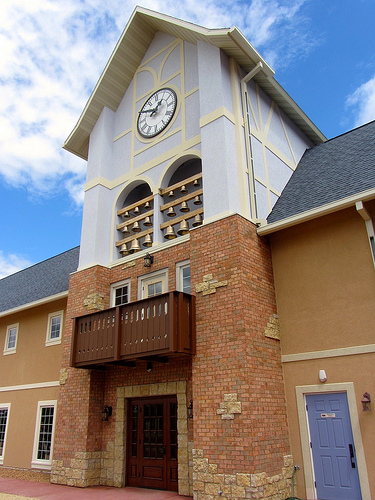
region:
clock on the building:
[128, 72, 192, 135]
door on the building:
[292, 377, 362, 498]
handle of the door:
[338, 437, 364, 476]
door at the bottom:
[117, 388, 187, 474]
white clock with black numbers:
[129, 85, 179, 142]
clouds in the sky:
[20, 87, 77, 143]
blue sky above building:
[321, 31, 357, 67]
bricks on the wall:
[213, 307, 246, 352]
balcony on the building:
[55, 290, 205, 376]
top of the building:
[119, 6, 170, 46]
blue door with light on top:
[289, 370, 373, 497]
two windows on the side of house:
[30, 304, 65, 483]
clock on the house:
[129, 83, 185, 139]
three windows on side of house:
[8, 310, 63, 469]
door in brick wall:
[94, 368, 199, 496]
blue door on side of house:
[290, 232, 374, 498]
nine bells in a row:
[112, 194, 152, 254]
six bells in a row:
[160, 179, 211, 215]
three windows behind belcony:
[67, 258, 202, 362]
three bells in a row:
[117, 199, 159, 220]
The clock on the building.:
[137, 87, 179, 138]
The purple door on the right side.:
[303, 391, 367, 498]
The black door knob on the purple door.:
[346, 438, 356, 471]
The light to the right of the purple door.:
[358, 385, 370, 417]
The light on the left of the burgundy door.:
[97, 400, 110, 424]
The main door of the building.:
[129, 397, 183, 492]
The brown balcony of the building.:
[68, 297, 192, 370]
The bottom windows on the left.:
[2, 403, 57, 467]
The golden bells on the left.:
[113, 181, 157, 251]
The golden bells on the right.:
[158, 169, 208, 238]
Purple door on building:
[303, 390, 360, 498]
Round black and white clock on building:
[136, 85, 179, 136]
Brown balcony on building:
[66, 278, 194, 360]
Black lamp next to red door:
[96, 401, 113, 420]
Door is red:
[122, 394, 179, 493]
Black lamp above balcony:
[139, 251, 155, 268]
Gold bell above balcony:
[162, 222, 177, 239]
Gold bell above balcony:
[141, 235, 152, 245]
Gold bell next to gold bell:
[180, 198, 190, 211]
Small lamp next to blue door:
[357, 390, 371, 412]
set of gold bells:
[109, 184, 154, 259]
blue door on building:
[301, 388, 362, 498]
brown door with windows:
[122, 395, 176, 489]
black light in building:
[141, 251, 152, 269]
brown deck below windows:
[67, 308, 196, 356]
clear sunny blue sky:
[2, 196, 76, 252]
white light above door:
[312, 364, 340, 384]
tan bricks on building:
[209, 387, 249, 427]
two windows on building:
[2, 388, 56, 479]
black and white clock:
[130, 75, 185, 138]